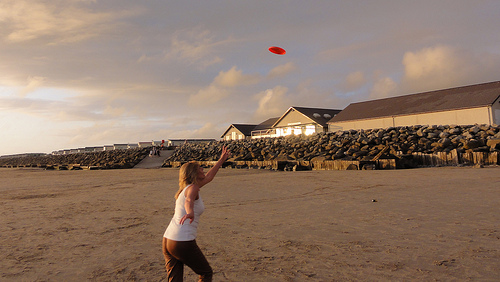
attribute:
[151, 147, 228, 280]
lady — light-skinned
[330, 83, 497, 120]
roof — brown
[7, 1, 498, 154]
sky — blue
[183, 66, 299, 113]
cloud — white, gray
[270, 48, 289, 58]
frisbee — in air, red, large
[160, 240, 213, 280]
pants — brown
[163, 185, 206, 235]
top — white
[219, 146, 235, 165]
left hand — in air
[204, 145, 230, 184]
arm — in air, raised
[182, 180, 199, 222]
arm — extended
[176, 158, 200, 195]
hair — blonde, brown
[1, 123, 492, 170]
rocks — piled, large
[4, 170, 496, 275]
beach — brown, in background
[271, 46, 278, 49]
logo — black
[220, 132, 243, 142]
doors — white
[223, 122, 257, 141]
house — brown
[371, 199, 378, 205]
rock — black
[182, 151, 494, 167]
barriers — brown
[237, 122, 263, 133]
roof — triangular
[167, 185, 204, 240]
shirt — white, short-sleeve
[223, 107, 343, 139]
houses — in background